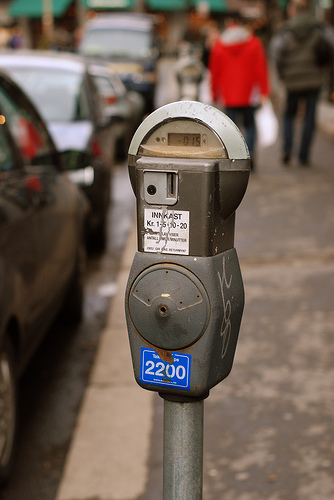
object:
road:
[42, 236, 93, 454]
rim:
[1, 362, 24, 474]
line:
[178, 299, 203, 311]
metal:
[156, 402, 207, 500]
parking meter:
[122, 94, 246, 412]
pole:
[156, 382, 206, 499]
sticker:
[139, 349, 191, 391]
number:
[145, 359, 155, 376]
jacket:
[207, 26, 268, 108]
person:
[207, 12, 290, 177]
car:
[0, 67, 94, 482]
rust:
[140, 337, 184, 363]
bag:
[253, 93, 279, 149]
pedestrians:
[271, 0, 331, 171]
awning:
[9, 0, 76, 16]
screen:
[166, 131, 202, 151]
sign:
[139, 345, 191, 390]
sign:
[142, 209, 190, 256]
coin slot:
[171, 173, 174, 195]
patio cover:
[121, 0, 213, 18]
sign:
[148, 107, 233, 165]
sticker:
[141, 207, 192, 253]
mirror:
[53, 147, 95, 190]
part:
[254, 162, 330, 496]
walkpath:
[259, 144, 331, 499]